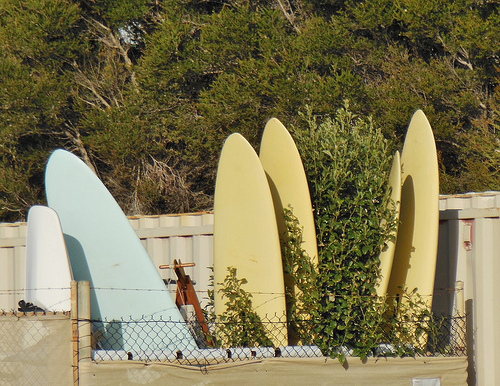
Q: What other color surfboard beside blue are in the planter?
A: Yellow.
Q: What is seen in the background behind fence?
A: Trees.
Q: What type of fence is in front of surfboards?
A: Chainlink.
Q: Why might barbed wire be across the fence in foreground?
A: To protect stealing surfboards.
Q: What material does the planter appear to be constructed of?
A: Wood.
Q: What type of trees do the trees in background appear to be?
A: Pines.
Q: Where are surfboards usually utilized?
A: In ocean.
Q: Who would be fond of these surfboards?
A: Surfer.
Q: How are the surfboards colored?
A: White, blue, and light yellow.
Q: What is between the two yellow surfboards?
A: A shrub.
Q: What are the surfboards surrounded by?
A: Two fences.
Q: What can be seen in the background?
A: Group of trees.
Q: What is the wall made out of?
A: Metal.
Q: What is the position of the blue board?
A: Bending down towards the white board.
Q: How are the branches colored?
A: Brown.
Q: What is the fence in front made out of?
A: Chain link.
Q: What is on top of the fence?
A: Barbed wire.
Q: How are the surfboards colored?
A: Blue, white, and yellow.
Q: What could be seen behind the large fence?
A: Trees.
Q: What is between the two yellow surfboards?
A: A large shrub.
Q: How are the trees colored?
A: Green.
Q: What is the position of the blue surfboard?
A: Bending down to the white surfboard.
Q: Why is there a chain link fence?
A: Somebody's private property.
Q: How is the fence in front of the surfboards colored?
A: Black and tan.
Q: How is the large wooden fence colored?
A: White.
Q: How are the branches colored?
A: Brown.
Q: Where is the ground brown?
A: Under the surfboards.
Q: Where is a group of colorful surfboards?
A: In the center of the photo.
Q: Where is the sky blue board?
A: On the left.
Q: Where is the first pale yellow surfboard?
A: On the left of the other 3 yellow ones.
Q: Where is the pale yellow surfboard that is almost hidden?
A: To the left of the first yellow one.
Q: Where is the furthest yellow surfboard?
A: On the right.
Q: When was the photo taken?
A: Daytime.